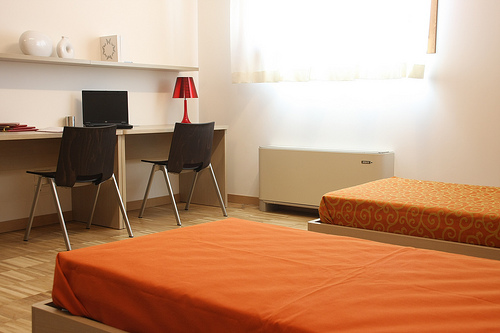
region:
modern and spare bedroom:
[12, 8, 493, 323]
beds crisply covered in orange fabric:
[51, 175, 492, 327]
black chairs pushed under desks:
[10, 116, 226, 246]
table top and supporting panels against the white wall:
[0, 106, 232, 221]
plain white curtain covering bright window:
[226, 1, 436, 81]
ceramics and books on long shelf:
[0, 26, 200, 71]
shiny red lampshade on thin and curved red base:
[166, 71, 196, 121]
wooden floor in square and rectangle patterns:
[0, 190, 306, 325]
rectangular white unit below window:
[250, 140, 400, 215]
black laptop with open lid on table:
[81, 85, 129, 131]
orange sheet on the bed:
[154, 243, 271, 299]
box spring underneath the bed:
[22, 300, 54, 325]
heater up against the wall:
[260, 140, 396, 175]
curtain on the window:
[228, 20, 442, 79]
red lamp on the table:
[168, 68, 199, 123]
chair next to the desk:
[135, 118, 237, 222]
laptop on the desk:
[77, 83, 137, 130]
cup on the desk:
[61, 105, 78, 126]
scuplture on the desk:
[92, 29, 122, 65]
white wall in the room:
[320, 105, 395, 134]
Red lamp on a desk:
[170, 75, 197, 125]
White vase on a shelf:
[58, 35, 75, 58]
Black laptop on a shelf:
[78, 87, 135, 129]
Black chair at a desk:
[133, 122, 226, 225]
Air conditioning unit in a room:
[253, 141, 395, 215]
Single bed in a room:
[308, 176, 499, 251]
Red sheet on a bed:
[38, 215, 499, 332]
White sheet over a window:
[216, 0, 434, 83]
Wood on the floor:
[0, 195, 310, 331]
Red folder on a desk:
[0, 120, 44, 131]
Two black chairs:
[25, 122, 232, 250]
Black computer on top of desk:
[77, 85, 134, 130]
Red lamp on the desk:
[171, 75, 201, 123]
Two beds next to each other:
[29, 177, 498, 331]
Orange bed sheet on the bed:
[55, 218, 498, 332]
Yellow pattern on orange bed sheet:
[321, 176, 498, 246]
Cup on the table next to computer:
[63, 115, 77, 127]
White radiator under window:
[255, 147, 395, 212]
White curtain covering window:
[225, 2, 438, 84]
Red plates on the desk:
[0, 122, 39, 131]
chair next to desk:
[148, 111, 246, 216]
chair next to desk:
[40, 120, 130, 230]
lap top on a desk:
[75, 80, 136, 120]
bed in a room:
[47, 227, 242, 302]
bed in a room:
[315, 185, 440, 230]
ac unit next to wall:
[240, 135, 305, 186]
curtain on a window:
[230, 45, 450, 90]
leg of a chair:
[50, 185, 70, 245]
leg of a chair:
[110, 180, 135, 225]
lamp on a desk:
[172, 71, 204, 126]